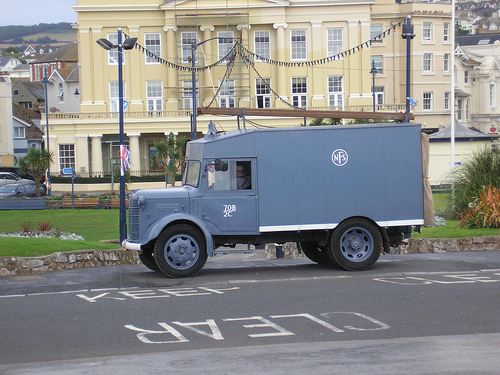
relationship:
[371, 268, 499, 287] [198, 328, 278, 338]
writing on pavement that says clear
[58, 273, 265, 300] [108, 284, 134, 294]
writing on pavement that says keep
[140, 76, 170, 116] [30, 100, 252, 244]
window on a building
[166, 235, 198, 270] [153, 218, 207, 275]
rim on tire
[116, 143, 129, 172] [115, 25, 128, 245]
flag on pole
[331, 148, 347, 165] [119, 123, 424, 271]
logo on truck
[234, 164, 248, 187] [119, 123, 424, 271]
driver of truck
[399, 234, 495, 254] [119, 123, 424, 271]
step behind truck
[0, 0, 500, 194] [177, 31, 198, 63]
building has window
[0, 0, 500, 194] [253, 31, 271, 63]
building has window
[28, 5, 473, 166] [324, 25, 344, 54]
building has window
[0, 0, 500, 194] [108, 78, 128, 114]
building has window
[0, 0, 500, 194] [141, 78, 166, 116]
building has window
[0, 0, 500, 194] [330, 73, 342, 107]
building has window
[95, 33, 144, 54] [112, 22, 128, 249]
lights on pole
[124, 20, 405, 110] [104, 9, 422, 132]
christmas lights on poles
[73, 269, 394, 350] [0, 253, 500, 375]
words on pavement